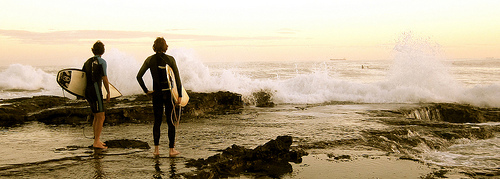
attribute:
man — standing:
[79, 40, 115, 153]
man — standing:
[135, 34, 187, 155]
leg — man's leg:
[93, 114, 103, 151]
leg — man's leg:
[152, 106, 163, 155]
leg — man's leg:
[164, 100, 179, 157]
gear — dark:
[78, 54, 113, 119]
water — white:
[399, 120, 476, 175]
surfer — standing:
[50, 26, 201, 163]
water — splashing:
[1, 59, 497, 105]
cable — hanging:
[168, 100, 182, 134]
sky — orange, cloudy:
[6, 2, 492, 54]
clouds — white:
[175, 13, 390, 54]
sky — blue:
[274, 6, 327, 46]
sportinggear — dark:
[136, 50, 183, 147]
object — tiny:
[354, 61, 370, 83]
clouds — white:
[2, 18, 257, 47]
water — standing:
[242, 69, 395, 109]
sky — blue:
[196, 1, 417, 41]